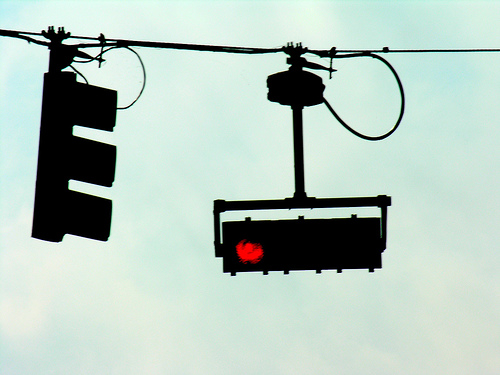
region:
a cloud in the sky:
[128, 302, 203, 371]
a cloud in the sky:
[362, 333, 389, 363]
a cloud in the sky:
[406, 260, 443, 312]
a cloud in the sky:
[192, 170, 237, 190]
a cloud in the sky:
[27, 253, 57, 300]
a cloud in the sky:
[432, 114, 465, 164]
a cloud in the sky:
[161, 98, 197, 133]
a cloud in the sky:
[119, 202, 158, 255]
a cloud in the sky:
[456, 67, 495, 112]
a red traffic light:
[235, 228, 266, 262]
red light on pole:
[238, 230, 275, 274]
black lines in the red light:
[242, 235, 262, 254]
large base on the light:
[197, 189, 239, 223]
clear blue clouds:
[148, 94, 210, 164]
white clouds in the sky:
[43, 255, 169, 348]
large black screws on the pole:
[268, 25, 317, 56]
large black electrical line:
[56, 18, 243, 73]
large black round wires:
[300, 39, 447, 158]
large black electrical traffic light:
[28, 56, 135, 257]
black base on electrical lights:
[18, 27, 100, 87]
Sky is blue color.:
[155, 98, 215, 174]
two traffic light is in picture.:
[25, 75, 390, 290]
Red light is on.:
[205, 215, 280, 271]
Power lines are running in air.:
[7, 15, 472, 100]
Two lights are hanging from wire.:
[15, 32, 435, 268]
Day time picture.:
[45, 21, 465, 347]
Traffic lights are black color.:
[25, 80, 410, 285]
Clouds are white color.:
[16, 285, 161, 340]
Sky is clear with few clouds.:
[31, 22, 466, 348]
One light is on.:
[212, 214, 283, 279]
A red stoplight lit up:
[213, 213, 294, 281]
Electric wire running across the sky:
[5, 21, 478, 70]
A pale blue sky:
[166, 11, 436, 145]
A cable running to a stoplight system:
[294, 42, 422, 141]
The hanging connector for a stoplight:
[249, 46, 324, 200]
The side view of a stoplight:
[31, 28, 121, 259]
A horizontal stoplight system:
[204, 194, 406, 276]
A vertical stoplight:
[21, 40, 131, 255]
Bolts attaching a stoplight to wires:
[34, 24, 76, 52]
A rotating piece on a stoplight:
[261, 59, 329, 114]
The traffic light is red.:
[215, 223, 273, 263]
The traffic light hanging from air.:
[206, 161, 403, 274]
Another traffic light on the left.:
[19, 58, 119, 255]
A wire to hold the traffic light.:
[93, 22, 458, 77]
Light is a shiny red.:
[233, 236, 267, 272]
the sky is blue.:
[180, 50, 440, 180]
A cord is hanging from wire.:
[331, 49, 432, 136]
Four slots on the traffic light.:
[227, 213, 419, 278]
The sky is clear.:
[168, 99, 461, 201]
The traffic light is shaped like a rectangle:
[213, 208, 438, 288]